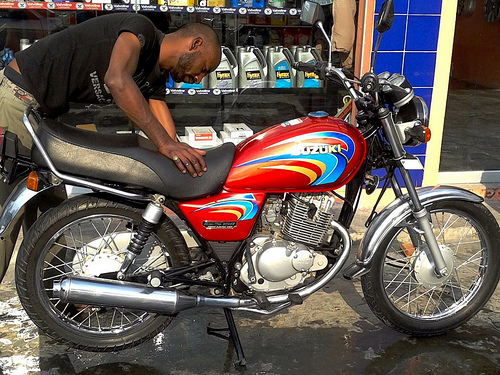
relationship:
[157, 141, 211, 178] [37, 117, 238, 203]
hand on seat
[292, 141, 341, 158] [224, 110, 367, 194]
emblem on tank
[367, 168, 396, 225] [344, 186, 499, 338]
brakes on wheel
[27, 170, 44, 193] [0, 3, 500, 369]
signal on motorbike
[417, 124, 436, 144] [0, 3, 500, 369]
signal on motorbike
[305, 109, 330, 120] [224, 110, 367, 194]
cap on tank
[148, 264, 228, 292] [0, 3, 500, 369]
kickstarter on motorbike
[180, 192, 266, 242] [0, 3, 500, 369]
guard on motorbike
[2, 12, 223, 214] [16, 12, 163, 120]
man wearing shirt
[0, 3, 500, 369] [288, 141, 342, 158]
motorbike has emblem